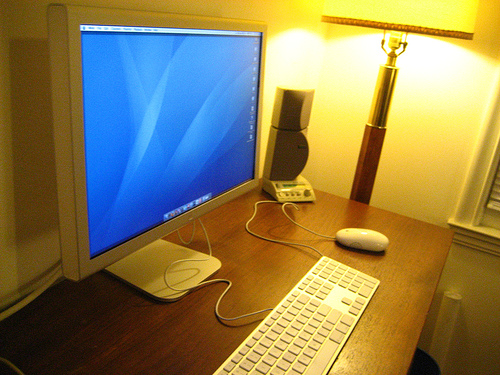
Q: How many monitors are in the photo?
A: One.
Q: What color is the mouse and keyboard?
A: White.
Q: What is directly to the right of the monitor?
A: Speaker.